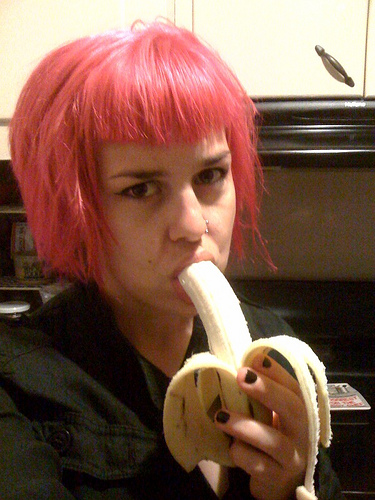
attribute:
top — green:
[1, 265, 346, 497]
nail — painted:
[242, 366, 266, 392]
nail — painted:
[213, 411, 235, 427]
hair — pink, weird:
[9, 16, 288, 292]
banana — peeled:
[188, 270, 323, 453]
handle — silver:
[289, 29, 372, 98]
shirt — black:
[21, 292, 258, 485]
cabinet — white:
[188, 12, 347, 99]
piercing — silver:
[195, 218, 227, 241]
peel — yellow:
[166, 357, 364, 490]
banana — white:
[166, 261, 258, 348]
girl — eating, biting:
[31, 65, 282, 418]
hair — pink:
[32, 40, 237, 224]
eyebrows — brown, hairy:
[109, 137, 235, 206]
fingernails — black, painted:
[201, 357, 292, 462]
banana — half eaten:
[156, 257, 290, 420]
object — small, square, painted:
[292, 378, 370, 431]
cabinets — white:
[219, 10, 373, 97]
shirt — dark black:
[41, 291, 285, 473]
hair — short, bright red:
[46, 60, 260, 251]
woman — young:
[40, 61, 266, 412]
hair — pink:
[41, 38, 274, 168]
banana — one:
[165, 245, 331, 480]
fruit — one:
[166, 257, 333, 492]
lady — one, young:
[6, 14, 335, 491]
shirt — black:
[6, 288, 276, 492]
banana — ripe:
[154, 250, 333, 493]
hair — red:
[45, 49, 196, 127]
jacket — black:
[8, 312, 155, 477]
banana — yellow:
[184, 265, 251, 357]